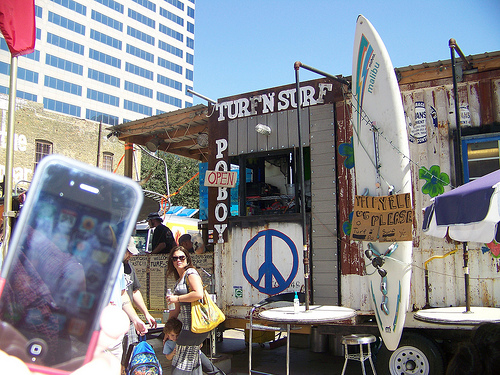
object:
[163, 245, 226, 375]
woman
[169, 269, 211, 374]
dress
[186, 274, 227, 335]
purse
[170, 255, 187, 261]
sunglasses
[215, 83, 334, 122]
sign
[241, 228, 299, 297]
peace symbol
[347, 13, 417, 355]
surfboard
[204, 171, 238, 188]
sign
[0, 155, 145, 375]
iphone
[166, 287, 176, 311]
bottle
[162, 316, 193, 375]
child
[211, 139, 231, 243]
sign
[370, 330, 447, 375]
tire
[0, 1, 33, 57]
flag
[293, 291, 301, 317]
bottle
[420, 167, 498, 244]
umbrella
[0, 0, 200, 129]
building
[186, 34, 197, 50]
window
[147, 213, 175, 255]
man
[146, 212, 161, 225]
hat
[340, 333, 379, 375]
stool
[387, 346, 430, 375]
rim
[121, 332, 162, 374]
backpack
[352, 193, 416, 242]
sign